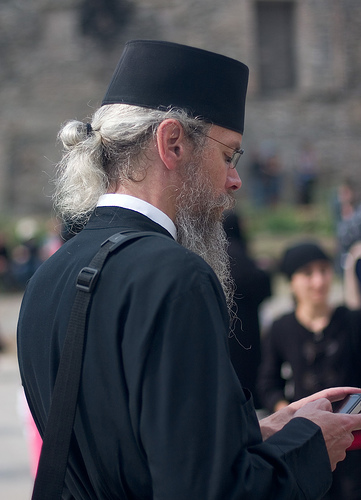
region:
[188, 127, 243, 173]
glasses on man's face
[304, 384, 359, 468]
cellphone in man's hands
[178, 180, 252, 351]
a long grey beard on man's face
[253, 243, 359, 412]
woman in black in background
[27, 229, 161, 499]
black strap over man's shoulder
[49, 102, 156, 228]
long grey hair tied in back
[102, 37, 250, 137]
a sturdy black hat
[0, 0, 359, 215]
a blurry grey building in background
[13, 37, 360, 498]
man in a black suit holding phone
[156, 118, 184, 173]
right ear of man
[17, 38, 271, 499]
man in black clothing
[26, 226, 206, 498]
bag strap on shoulder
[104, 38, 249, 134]
cap with flat top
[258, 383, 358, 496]
cell phone in hands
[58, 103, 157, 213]
pony tail in gray hair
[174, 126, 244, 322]
long beard on face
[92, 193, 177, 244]
white collar of shirt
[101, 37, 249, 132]
plain black cap on head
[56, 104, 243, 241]
man with gray hair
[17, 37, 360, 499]
Man reading his mobile device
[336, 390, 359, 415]
Mobile device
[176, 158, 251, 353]
Long grey beard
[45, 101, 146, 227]
Grey pony tail hair style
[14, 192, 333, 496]
Man's navy blue suit jacket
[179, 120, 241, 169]
Men's wire rim glasses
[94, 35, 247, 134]
Man's round black hat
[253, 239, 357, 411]
Man walking towards man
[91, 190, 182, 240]
Dressy white shirt collar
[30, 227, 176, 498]
Black over-shoulder bag strap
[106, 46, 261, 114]
A black hat in the photo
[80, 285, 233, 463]
a black shirt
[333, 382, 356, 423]
A mobile phone in the photo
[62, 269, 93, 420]
A bag in the photo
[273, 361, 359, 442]
A mobile phone in the hands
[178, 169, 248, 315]
Long beard in the photo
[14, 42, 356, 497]
A man standing in the photo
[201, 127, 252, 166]
Eyeglasses in the photo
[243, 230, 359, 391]
A woman in the background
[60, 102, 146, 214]
Gray hair in the photo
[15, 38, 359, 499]
man wears suit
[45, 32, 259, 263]
head supports fez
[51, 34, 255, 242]
fez sits on head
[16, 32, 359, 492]
man looks at phone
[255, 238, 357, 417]
woman is in the background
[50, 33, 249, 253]
man wears glasses to see better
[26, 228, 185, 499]
strap holds a container of some sort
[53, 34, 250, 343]
face has a beard on it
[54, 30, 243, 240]
long hair is under the hat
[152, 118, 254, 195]
glasses rest on ears and nose